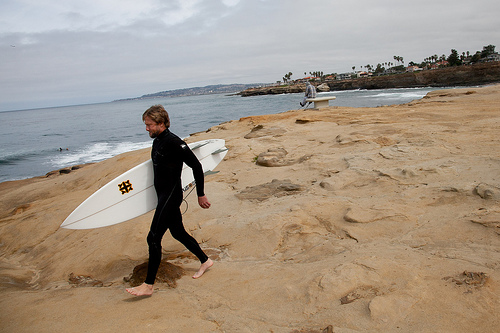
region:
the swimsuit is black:
[150, 129, 210, 271]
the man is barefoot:
[133, 106, 218, 300]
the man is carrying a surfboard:
[126, 107, 218, 307]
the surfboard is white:
[64, 134, 240, 231]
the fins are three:
[191, 133, 243, 178]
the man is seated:
[296, 81, 332, 105]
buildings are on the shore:
[396, 56, 454, 73]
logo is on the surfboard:
[117, 177, 130, 196]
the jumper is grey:
[303, 83, 315, 99]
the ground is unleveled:
[261, 123, 459, 329]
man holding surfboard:
[57, 86, 227, 303]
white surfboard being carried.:
[59, 135, 227, 233]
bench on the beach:
[302, 93, 341, 108]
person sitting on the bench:
[298, 72, 317, 109]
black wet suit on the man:
[128, 102, 220, 297]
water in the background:
[4, 91, 443, 181]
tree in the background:
[446, 45, 460, 67]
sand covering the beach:
[3, 78, 498, 330]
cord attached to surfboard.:
[179, 183, 203, 218]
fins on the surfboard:
[190, 136, 226, 181]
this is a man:
[146, 139, 204, 302]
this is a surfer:
[105, 129, 209, 279]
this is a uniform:
[149, 211, 169, 225]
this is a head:
[115, 90, 178, 166]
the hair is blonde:
[143, 74, 153, 92]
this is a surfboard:
[89, 200, 100, 214]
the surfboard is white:
[85, 166, 153, 281]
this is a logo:
[103, 154, 158, 197]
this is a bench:
[297, 91, 334, 143]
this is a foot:
[135, 253, 174, 325]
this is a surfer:
[46, 93, 236, 325]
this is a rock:
[306, 216, 439, 281]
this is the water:
[60, 110, 134, 138]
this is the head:
[139, 109, 175, 136]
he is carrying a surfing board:
[57, 100, 264, 246]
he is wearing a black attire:
[129, 72, 231, 298]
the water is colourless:
[186, 100, 248, 115]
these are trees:
[447, 52, 458, 62]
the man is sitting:
[292, 76, 332, 109]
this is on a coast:
[15, 40, 445, 269]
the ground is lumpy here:
[260, 151, 448, 271]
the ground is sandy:
[255, 181, 437, 293]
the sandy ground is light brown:
[300, 188, 476, 303]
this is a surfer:
[99, 94, 236, 243]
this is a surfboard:
[48, 126, 143, 219]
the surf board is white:
[78, 178, 160, 241]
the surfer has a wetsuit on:
[133, 119, 218, 284]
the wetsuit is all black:
[128, 118, 223, 259]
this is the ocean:
[40, 109, 129, 164]